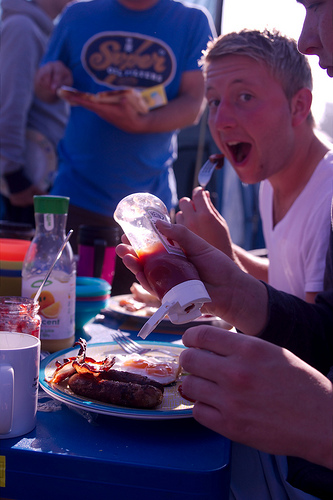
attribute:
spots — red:
[222, 372, 244, 430]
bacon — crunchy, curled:
[70, 336, 108, 381]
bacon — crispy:
[49, 336, 118, 386]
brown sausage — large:
[67, 371, 161, 406]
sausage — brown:
[66, 361, 165, 413]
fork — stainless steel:
[197, 157, 215, 188]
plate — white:
[37, 333, 199, 420]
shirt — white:
[120, 6, 328, 343]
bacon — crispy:
[59, 332, 125, 381]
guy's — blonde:
[259, 92, 327, 196]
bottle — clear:
[16, 188, 104, 352]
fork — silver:
[111, 330, 180, 358]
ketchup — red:
[183, 302, 194, 312]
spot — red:
[254, 161, 267, 172]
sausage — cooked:
[71, 374, 161, 411]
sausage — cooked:
[69, 364, 166, 403]